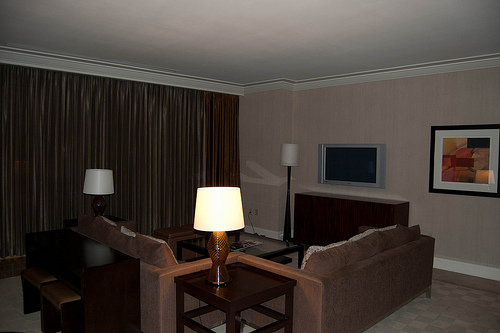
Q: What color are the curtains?
A: Brown.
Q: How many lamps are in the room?
A: 3.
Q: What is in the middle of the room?
A: A coffee table.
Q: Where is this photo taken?
A: In the living room.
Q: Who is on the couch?
A: No one.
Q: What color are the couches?
A: Tan.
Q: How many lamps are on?
A: 1.